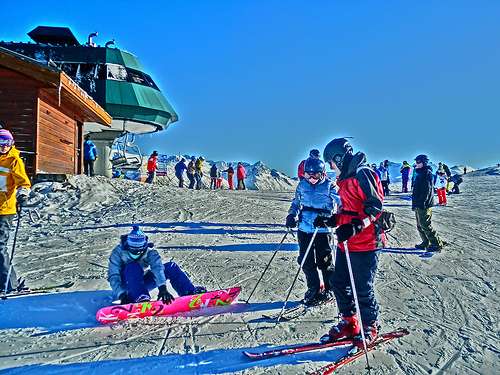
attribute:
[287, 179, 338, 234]
jacket — blue 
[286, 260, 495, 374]
snow — white 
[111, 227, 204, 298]
person — sitting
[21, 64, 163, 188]
building — brown , wooden 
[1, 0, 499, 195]
sky — blue 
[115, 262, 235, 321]
pants — blue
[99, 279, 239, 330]
snowboard — pink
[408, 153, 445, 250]
person — standing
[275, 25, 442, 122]
skies — blue , clear 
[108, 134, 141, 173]
ski lift — white , metal 